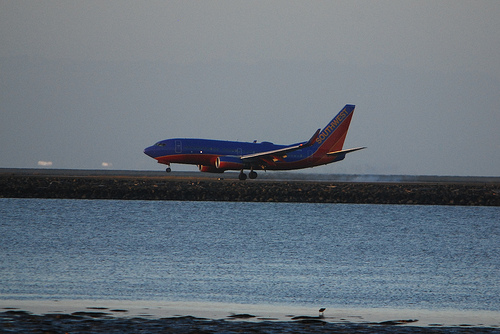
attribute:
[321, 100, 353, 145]
tail — Red, blue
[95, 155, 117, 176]
object — white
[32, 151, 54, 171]
object — white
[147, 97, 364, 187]
plane — blue, Red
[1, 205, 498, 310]
water — large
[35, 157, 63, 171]
object — white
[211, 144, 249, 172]
engine — Red, blue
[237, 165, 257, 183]
wheel — black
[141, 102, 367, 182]
plane — low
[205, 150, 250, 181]
engine — blue , Red 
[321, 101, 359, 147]
word — yellow